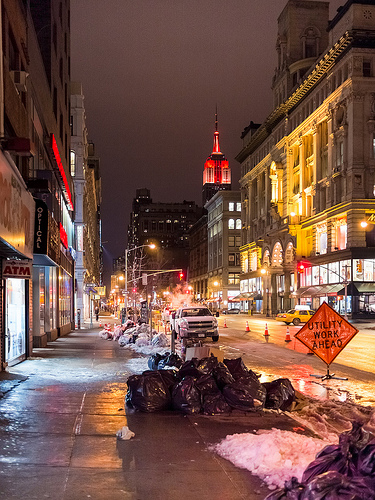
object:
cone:
[245, 317, 251, 331]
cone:
[263, 323, 268, 335]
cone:
[285, 326, 290, 339]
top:
[203, 107, 232, 187]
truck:
[170, 305, 218, 347]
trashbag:
[259, 378, 293, 411]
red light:
[297, 261, 308, 277]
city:
[0, 0, 375, 500]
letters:
[0, 264, 28, 275]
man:
[94, 305, 98, 319]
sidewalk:
[0, 309, 322, 498]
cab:
[273, 307, 316, 326]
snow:
[222, 415, 320, 481]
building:
[197, 101, 233, 210]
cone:
[219, 315, 228, 328]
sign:
[3, 263, 34, 280]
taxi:
[275, 305, 316, 328]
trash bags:
[118, 344, 294, 429]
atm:
[0, 349, 53, 401]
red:
[56, 225, 82, 267]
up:
[83, 185, 91, 300]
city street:
[0, 292, 375, 500]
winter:
[211, 429, 324, 482]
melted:
[210, 425, 295, 495]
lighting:
[251, 148, 313, 237]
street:
[214, 304, 374, 400]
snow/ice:
[97, 308, 341, 489]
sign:
[295, 299, 357, 367]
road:
[0, 292, 373, 500]